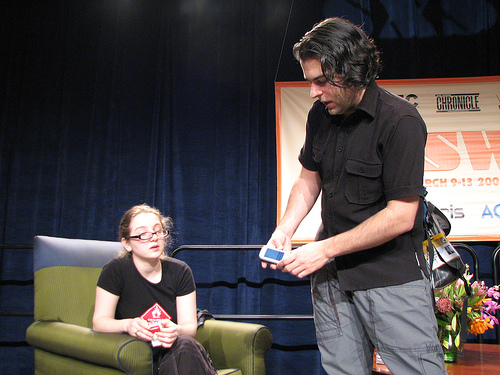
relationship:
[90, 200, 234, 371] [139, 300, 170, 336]
girl holding red card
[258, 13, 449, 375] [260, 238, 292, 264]
man looking at phone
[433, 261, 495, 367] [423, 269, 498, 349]
vase full of flowers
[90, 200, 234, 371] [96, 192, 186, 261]
girl with blonde hair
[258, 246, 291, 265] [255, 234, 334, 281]
cell phone in a hand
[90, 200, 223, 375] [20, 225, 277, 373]
girl sitting in chair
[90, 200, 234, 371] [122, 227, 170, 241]
girl wearing glasses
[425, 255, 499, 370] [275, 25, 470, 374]
flowers behind man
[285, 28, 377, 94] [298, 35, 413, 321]
face on man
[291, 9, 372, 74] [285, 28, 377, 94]
black hair on face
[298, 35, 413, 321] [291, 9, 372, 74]
man has black hair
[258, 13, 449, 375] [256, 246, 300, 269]
man demonstrating cell phone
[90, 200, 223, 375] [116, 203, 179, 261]
girl has blonde hair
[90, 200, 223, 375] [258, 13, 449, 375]
girl looking at man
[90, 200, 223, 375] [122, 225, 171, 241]
girl wearing glasses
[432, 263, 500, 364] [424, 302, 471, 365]
flowers in vase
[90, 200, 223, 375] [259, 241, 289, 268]
girl looking at cell phone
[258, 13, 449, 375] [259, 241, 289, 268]
man looking at cell phone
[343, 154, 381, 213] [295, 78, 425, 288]
pocket in shirt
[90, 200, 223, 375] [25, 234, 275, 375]
girl sitting on chair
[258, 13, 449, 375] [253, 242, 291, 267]
man holding phone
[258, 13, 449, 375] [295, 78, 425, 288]
man wearing shirt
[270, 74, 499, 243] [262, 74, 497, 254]
orange trim on sign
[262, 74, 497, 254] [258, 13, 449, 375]
sign behind man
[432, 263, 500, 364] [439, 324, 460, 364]
flowers in vase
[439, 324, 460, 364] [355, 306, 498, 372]
vase on table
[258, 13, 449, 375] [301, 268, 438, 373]
man wearing pants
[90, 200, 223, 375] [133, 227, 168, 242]
girl wearing glasses